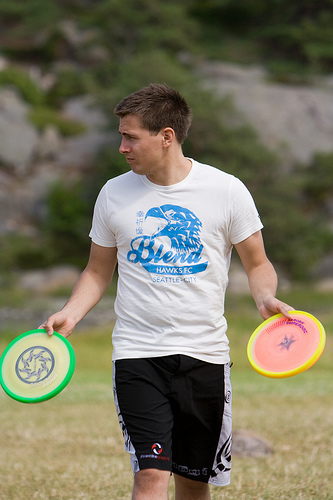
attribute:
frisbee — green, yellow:
[0, 328, 76, 403]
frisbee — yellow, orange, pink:
[246, 310, 326, 379]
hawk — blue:
[144, 205, 203, 250]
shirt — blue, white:
[88, 157, 262, 367]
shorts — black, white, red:
[112, 353, 233, 488]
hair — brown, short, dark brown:
[114, 82, 192, 145]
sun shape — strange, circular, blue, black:
[18, 348, 53, 384]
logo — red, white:
[152, 442, 162, 456]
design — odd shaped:
[277, 336, 296, 352]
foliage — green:
[0, 1, 331, 278]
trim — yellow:
[246, 310, 327, 380]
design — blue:
[127, 203, 208, 275]